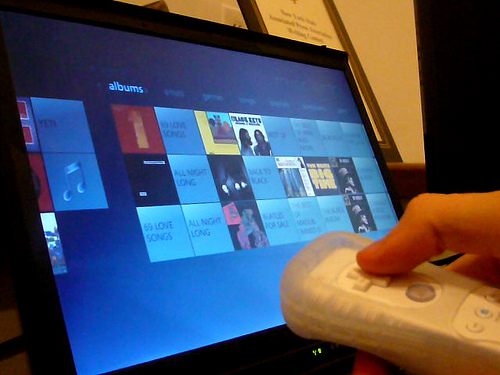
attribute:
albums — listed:
[93, 93, 402, 246]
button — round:
[412, 267, 452, 319]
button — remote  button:
[318, 247, 465, 338]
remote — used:
[263, 207, 494, 369]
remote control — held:
[277, 228, 498, 372]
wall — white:
[338, 4, 451, 179]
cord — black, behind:
[2, 329, 27, 354]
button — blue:
[471, 295, 492, 327]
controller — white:
[275, 220, 499, 370]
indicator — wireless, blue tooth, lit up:
[311, 347, 316, 358]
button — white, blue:
[390, 272, 498, 362]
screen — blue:
[3, 10, 401, 375]